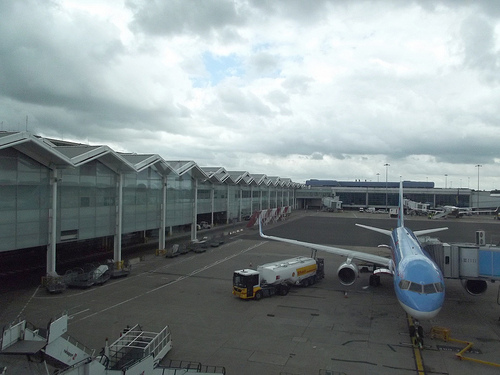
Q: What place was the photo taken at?
A: It was taken at the airport.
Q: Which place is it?
A: It is an airport.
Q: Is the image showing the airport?
A: Yes, it is showing the airport.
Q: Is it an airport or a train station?
A: It is an airport.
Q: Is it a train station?
A: No, it is an airport.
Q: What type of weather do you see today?
A: It is cloudy.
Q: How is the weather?
A: It is cloudy.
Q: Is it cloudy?
A: Yes, it is cloudy.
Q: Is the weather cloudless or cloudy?
A: It is cloudy.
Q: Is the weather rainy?
A: No, it is cloudy.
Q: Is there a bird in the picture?
A: No, there are no birds.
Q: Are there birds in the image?
A: No, there are no birds.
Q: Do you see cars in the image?
A: No, there are no cars.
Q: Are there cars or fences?
A: No, there are no cars or fences.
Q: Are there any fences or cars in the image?
A: No, there are no cars or fences.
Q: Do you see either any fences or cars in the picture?
A: No, there are no cars or fences.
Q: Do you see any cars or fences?
A: No, there are no cars or fences.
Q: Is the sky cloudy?
A: Yes, the sky is cloudy.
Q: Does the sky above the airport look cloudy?
A: Yes, the sky is cloudy.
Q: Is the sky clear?
A: No, the sky is cloudy.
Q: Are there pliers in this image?
A: No, there are no pliers.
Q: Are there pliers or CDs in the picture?
A: No, there are no pliers or cds.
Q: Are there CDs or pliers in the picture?
A: No, there are no pliers or cds.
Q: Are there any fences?
A: No, there are no fences.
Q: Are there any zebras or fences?
A: No, there are no fences or zebras.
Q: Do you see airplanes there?
A: Yes, there is an airplane.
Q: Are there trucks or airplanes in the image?
A: Yes, there is an airplane.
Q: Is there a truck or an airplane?
A: Yes, there is an airplane.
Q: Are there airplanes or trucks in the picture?
A: Yes, there is an airplane.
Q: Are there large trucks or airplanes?
A: Yes, there is a large airplane.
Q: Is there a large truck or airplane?
A: Yes, there is a large airplane.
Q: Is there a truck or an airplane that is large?
A: Yes, the airplane is large.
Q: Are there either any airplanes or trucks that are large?
A: Yes, the airplane is large.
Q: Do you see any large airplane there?
A: Yes, there is a large airplane.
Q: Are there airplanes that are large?
A: Yes, there is an airplane that is large.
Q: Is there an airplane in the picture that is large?
A: Yes, there is an airplane that is large.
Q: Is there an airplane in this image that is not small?
A: Yes, there is a large airplane.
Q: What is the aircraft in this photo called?
A: The aircraft is an airplane.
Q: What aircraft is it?
A: The aircraft is an airplane.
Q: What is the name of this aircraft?
A: This is an airplane.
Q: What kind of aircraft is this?
A: This is an airplane.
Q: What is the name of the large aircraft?
A: The aircraft is an airplane.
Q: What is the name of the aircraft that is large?
A: The aircraft is an airplane.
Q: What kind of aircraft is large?
A: The aircraft is an airplane.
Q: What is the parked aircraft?
A: The aircraft is an airplane.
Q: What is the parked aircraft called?
A: The aircraft is an airplane.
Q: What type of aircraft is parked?
A: The aircraft is an airplane.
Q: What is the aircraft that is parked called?
A: The aircraft is an airplane.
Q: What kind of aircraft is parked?
A: The aircraft is an airplane.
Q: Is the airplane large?
A: Yes, the airplane is large.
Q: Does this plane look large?
A: Yes, the plane is large.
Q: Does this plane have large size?
A: Yes, the plane is large.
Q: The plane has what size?
A: The plane is large.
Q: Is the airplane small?
A: No, the airplane is large.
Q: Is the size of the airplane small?
A: No, the airplane is large.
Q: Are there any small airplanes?
A: No, there is an airplane but it is large.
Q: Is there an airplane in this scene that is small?
A: No, there is an airplane but it is large.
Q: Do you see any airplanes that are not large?
A: No, there is an airplane but it is large.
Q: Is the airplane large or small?
A: The airplane is large.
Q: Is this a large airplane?
A: Yes, this is a large airplane.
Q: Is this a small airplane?
A: No, this is a large airplane.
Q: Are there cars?
A: No, there are no cars.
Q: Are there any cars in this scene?
A: No, there are no cars.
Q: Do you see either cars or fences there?
A: No, there are no cars or fences.